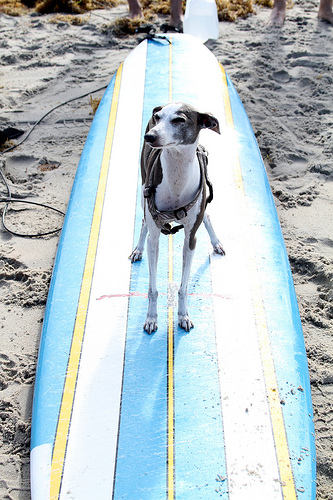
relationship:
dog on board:
[125, 97, 226, 342] [24, 28, 321, 497]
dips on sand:
[0, 270, 46, 308] [0, 6, 319, 498]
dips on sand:
[275, 153, 310, 194] [284, 118, 316, 195]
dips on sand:
[290, 249, 332, 332] [12, 197, 322, 447]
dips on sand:
[27, 30, 61, 78] [2, 31, 319, 387]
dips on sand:
[5, 357, 28, 393] [0, 6, 319, 498]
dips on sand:
[0, 270, 46, 308] [1, 78, 229, 292]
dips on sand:
[267, 154, 312, 198] [0, 6, 319, 498]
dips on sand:
[290, 249, 332, 332] [0, 6, 319, 498]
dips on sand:
[301, 245, 322, 284] [0, 6, 319, 498]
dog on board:
[111, 98, 239, 362] [24, 28, 321, 497]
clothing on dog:
[139, 120, 217, 248] [111, 98, 239, 362]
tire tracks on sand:
[21, 75, 119, 154] [0, 6, 319, 498]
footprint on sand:
[268, 66, 291, 86] [0, 6, 319, 498]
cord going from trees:
[2, 71, 120, 256] [17, 3, 291, 41]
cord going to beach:
[2, 71, 120, 256] [5, 244, 322, 443]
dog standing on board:
[125, 97, 226, 342] [24, 28, 321, 497]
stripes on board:
[59, 39, 147, 500] [24, 28, 321, 497]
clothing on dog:
[139, 120, 217, 250] [125, 97, 226, 342]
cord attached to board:
[0, 82, 110, 242] [24, 28, 321, 497]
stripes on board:
[25, 67, 115, 453] [24, 28, 321, 497]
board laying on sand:
[24, 28, 321, 497] [0, 6, 319, 498]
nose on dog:
[141, 128, 157, 144] [125, 97, 226, 342]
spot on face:
[155, 102, 186, 147] [144, 102, 198, 152]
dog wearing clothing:
[125, 97, 226, 342] [139, 120, 217, 250]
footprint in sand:
[268, 66, 291, 86] [240, 39, 321, 104]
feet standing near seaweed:
[122, 1, 184, 27] [2, 1, 278, 19]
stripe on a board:
[165, 33, 177, 495] [24, 28, 321, 497]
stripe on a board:
[163, 61, 178, 495] [24, 28, 321, 497]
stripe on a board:
[175, 282, 229, 497] [24, 28, 321, 497]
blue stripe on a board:
[269, 318, 308, 483] [24, 28, 321, 497]